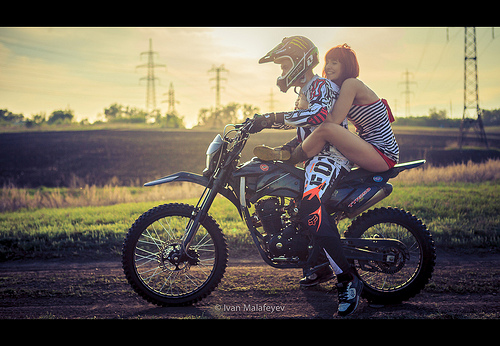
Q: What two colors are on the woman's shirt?
A: Black and white.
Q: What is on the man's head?
A: Helmet.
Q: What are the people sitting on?
A: Motorbike.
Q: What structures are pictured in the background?
A: Electric towers.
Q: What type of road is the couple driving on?
A: Dirt.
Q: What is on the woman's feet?
A: Boots.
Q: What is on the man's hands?
A: Gloves.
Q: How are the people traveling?
A: By bike.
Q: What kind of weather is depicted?
A: Sunny and warm.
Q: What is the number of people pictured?
A: 2.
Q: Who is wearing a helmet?
A: Driver.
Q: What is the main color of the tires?
A: Black.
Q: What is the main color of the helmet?
A: Black and white.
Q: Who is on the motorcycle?
A: Young couple.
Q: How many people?
A: 2.